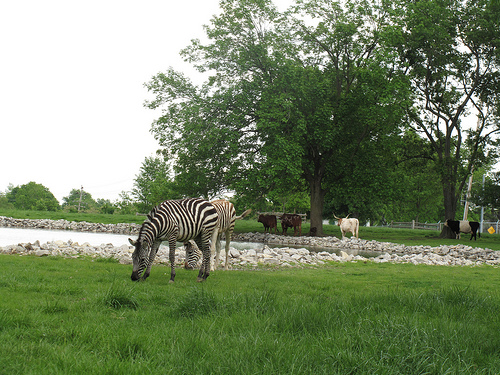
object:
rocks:
[239, 251, 261, 262]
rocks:
[303, 250, 326, 261]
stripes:
[172, 203, 186, 237]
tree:
[131, 155, 175, 215]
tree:
[7, 180, 59, 210]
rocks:
[342, 252, 348, 266]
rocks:
[294, 245, 309, 255]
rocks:
[243, 250, 253, 257]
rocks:
[377, 252, 385, 263]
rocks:
[292, 254, 302, 259]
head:
[125, 237, 153, 281]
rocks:
[40, 241, 55, 247]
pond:
[0, 227, 427, 259]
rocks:
[106, 241, 118, 248]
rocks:
[123, 252, 130, 264]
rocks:
[69, 241, 79, 246]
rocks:
[51, 249, 66, 255]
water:
[3, 228, 398, 258]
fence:
[378, 214, 500, 236]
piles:
[0, 215, 499, 267]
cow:
[278, 212, 303, 236]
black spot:
[309, 227, 317, 234]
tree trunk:
[308, 136, 324, 238]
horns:
[345, 213, 352, 219]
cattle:
[332, 212, 360, 239]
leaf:
[208, 136, 224, 147]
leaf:
[186, 146, 196, 153]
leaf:
[188, 102, 197, 112]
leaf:
[193, 161, 205, 175]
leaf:
[279, 89, 294, 108]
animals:
[257, 214, 278, 234]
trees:
[63, 184, 94, 211]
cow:
[258, 213, 278, 235]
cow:
[444, 219, 481, 241]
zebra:
[183, 198, 250, 269]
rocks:
[28, 246, 45, 258]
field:
[0, 205, 499, 372]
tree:
[244, 54, 416, 236]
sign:
[488, 225, 497, 235]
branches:
[438, 96, 464, 189]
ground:
[0, 210, 499, 374]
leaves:
[332, 155, 349, 168]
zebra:
[126, 198, 222, 284]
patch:
[349, 221, 353, 226]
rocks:
[32, 242, 101, 258]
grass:
[0, 255, 496, 372]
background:
[0, 0, 499, 237]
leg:
[166, 238, 177, 286]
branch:
[457, 118, 490, 196]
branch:
[448, 56, 482, 131]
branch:
[332, 120, 372, 187]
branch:
[416, 2, 461, 142]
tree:
[368, 0, 499, 242]